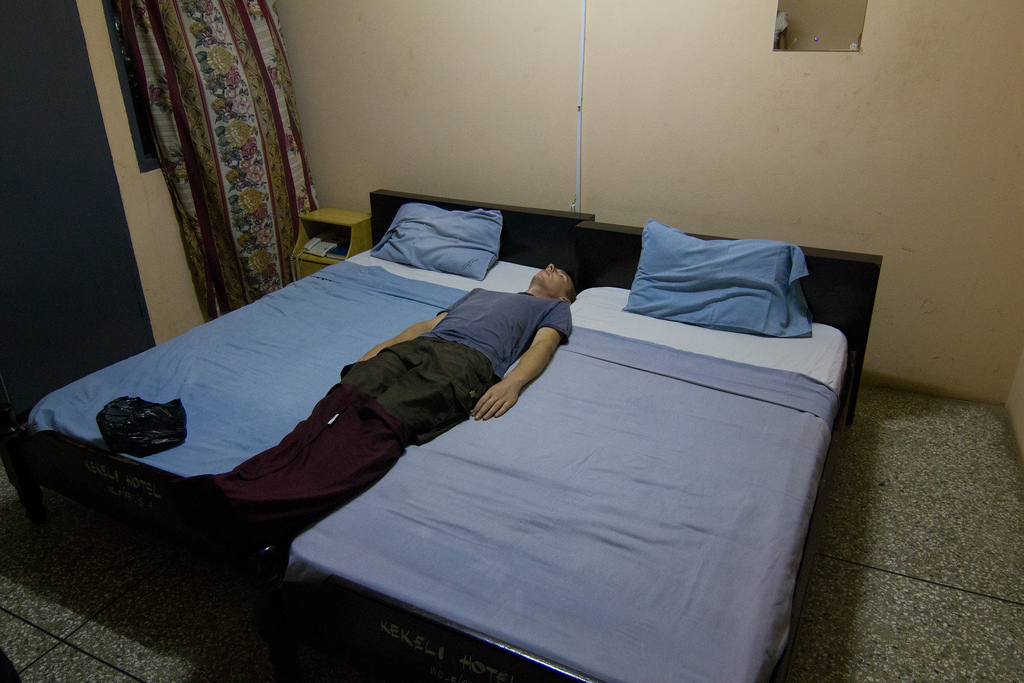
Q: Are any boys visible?
A: No, there are no boys.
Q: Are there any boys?
A: No, there are no boys.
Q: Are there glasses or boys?
A: No, there are no boys or glasses.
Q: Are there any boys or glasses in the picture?
A: No, there are no boys or glasses.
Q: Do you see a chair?
A: No, there are no chairs.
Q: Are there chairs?
A: No, there are no chairs.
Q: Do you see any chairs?
A: No, there are no chairs.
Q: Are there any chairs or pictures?
A: No, there are no chairs or pictures.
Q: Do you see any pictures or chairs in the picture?
A: No, there are no chairs or pictures.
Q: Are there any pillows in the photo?
A: Yes, there is a pillow.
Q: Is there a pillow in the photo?
A: Yes, there is a pillow.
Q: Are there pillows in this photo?
A: Yes, there is a pillow.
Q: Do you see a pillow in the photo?
A: Yes, there is a pillow.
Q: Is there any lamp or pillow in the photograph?
A: Yes, there is a pillow.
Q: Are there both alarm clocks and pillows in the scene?
A: No, there is a pillow but no alarm clocks.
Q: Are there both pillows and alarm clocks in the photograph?
A: No, there is a pillow but no alarm clocks.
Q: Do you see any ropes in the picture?
A: No, there are no ropes.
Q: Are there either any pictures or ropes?
A: No, there are no ropes or pictures.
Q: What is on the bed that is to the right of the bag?
A: The pillow is on the bed.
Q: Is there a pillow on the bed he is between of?
A: Yes, there is a pillow on the bed.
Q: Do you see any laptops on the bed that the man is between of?
A: No, there is a pillow on the bed.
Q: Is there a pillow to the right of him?
A: Yes, there is a pillow to the right of the man.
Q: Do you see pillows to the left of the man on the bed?
A: No, the pillow is to the right of the man.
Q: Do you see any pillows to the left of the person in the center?
A: No, the pillow is to the right of the man.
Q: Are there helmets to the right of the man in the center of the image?
A: No, there is a pillow to the right of the man.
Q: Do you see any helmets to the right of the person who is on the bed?
A: No, there is a pillow to the right of the man.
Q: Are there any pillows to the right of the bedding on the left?
A: Yes, there is a pillow to the right of the bedding.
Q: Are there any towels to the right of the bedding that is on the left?
A: No, there is a pillow to the right of the bedding.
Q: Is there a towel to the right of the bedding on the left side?
A: No, there is a pillow to the right of the bedding.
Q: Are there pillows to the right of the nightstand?
A: Yes, there is a pillow to the right of the nightstand.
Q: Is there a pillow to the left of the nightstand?
A: No, the pillow is to the right of the nightstand.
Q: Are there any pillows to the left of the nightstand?
A: No, the pillow is to the right of the nightstand.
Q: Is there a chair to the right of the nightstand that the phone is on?
A: No, there is a pillow to the right of the nightstand.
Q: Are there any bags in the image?
A: Yes, there is a bag.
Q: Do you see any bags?
A: Yes, there is a bag.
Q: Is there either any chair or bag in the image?
A: Yes, there is a bag.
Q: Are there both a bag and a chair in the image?
A: No, there is a bag but no chairs.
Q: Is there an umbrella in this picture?
A: No, there are no umbrellas.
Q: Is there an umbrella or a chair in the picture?
A: No, there are no umbrellas or chairs.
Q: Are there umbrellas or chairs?
A: No, there are no umbrellas or chairs.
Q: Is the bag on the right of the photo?
A: No, the bag is on the left of the image.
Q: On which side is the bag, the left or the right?
A: The bag is on the left of the image.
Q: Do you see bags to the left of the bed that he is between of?
A: Yes, there is a bag to the left of the bed.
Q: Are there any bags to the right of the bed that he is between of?
A: No, the bag is to the left of the bed.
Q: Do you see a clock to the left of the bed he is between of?
A: No, there is a bag to the left of the bed.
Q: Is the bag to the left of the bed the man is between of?
A: Yes, the bag is to the left of the bed.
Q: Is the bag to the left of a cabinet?
A: No, the bag is to the left of the bed.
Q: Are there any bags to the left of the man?
A: Yes, there is a bag to the left of the man.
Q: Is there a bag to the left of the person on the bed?
A: Yes, there is a bag to the left of the man.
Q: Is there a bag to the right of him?
A: No, the bag is to the left of the man.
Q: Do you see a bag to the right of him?
A: No, the bag is to the left of the man.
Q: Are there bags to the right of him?
A: No, the bag is to the left of the man.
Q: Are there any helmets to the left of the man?
A: No, there is a bag to the left of the man.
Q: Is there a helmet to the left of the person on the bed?
A: No, there is a bag to the left of the man.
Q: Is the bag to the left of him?
A: Yes, the bag is to the left of the man.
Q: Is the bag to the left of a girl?
A: No, the bag is to the left of the man.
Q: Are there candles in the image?
A: No, there are no candles.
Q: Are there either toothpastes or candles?
A: No, there are no candles or toothpastes.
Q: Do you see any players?
A: No, there are no players.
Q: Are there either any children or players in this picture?
A: No, there are no players or children.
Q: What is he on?
A: The man is on the bed.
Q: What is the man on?
A: The man is on the bed.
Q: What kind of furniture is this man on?
A: The man is on the bed.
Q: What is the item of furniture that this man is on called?
A: The piece of furniture is a bed.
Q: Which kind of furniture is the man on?
A: The man is on the bed.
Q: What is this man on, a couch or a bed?
A: The man is on a bed.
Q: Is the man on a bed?
A: Yes, the man is on a bed.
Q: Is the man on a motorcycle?
A: No, the man is on a bed.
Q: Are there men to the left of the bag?
A: No, the man is to the right of the bag.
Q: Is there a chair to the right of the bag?
A: No, there is a man to the right of the bag.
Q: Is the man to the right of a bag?
A: Yes, the man is to the right of a bag.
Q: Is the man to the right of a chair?
A: No, the man is to the right of a bag.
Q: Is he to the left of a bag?
A: No, the man is to the right of a bag.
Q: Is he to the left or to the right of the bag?
A: The man is to the right of the bag.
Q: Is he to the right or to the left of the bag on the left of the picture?
A: The man is to the right of the bag.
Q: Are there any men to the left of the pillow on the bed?
A: Yes, there is a man to the left of the pillow.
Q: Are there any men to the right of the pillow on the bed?
A: No, the man is to the left of the pillow.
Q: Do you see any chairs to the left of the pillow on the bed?
A: No, there is a man to the left of the pillow.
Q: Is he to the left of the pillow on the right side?
A: Yes, the man is to the left of the pillow.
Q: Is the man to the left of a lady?
A: No, the man is to the left of the pillow.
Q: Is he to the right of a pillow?
A: No, the man is to the left of a pillow.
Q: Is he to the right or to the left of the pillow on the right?
A: The man is to the left of the pillow.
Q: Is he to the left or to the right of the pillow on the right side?
A: The man is to the left of the pillow.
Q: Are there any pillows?
A: Yes, there is a pillow.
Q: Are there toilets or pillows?
A: Yes, there is a pillow.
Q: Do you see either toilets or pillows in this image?
A: Yes, there is a pillow.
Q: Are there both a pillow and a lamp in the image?
A: No, there is a pillow but no lamps.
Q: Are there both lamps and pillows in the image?
A: No, there is a pillow but no lamps.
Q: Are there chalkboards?
A: No, there are no chalkboards.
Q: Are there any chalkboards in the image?
A: No, there are no chalkboards.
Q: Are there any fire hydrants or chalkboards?
A: No, there are no chalkboards or fire hydrants.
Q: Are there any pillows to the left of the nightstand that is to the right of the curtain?
A: No, the pillow is to the right of the nightstand.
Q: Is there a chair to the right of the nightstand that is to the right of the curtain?
A: No, there is a pillow to the right of the nightstand.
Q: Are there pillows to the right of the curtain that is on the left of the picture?
A: Yes, there is a pillow to the right of the curtain.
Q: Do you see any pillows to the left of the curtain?
A: No, the pillow is to the right of the curtain.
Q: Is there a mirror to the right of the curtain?
A: No, there is a pillow to the right of the curtain.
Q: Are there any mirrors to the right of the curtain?
A: No, there is a pillow to the right of the curtain.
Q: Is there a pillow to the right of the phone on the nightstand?
A: Yes, there is a pillow to the right of the telephone.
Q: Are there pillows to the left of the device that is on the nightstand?
A: No, the pillow is to the right of the phone.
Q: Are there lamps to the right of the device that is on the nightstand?
A: No, there is a pillow to the right of the telephone.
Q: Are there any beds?
A: Yes, there is a bed.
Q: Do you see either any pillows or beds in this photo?
A: Yes, there is a bed.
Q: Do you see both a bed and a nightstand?
A: Yes, there are both a bed and a nightstand.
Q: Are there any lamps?
A: No, there are no lamps.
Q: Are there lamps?
A: No, there are no lamps.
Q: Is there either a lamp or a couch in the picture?
A: No, there are no lamps or couches.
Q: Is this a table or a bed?
A: This is a bed.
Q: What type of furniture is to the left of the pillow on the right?
A: The piece of furniture is a bed.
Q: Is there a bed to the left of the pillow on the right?
A: Yes, there is a bed to the left of the pillow.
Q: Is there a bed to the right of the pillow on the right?
A: No, the bed is to the left of the pillow.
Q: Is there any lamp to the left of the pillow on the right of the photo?
A: No, there is a bed to the left of the pillow.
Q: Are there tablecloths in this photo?
A: No, there are no tablecloths.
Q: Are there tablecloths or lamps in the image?
A: No, there are no tablecloths or lamps.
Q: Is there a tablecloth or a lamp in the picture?
A: No, there are no tablecloths or lamps.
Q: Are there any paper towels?
A: No, there are no paper towels.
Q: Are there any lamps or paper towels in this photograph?
A: No, there are no paper towels or lamps.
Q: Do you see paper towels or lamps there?
A: No, there are no paper towels or lamps.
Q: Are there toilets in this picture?
A: No, there are no toilets.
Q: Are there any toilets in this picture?
A: No, there are no toilets.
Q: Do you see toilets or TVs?
A: No, there are no toilets or tvs.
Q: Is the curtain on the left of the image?
A: Yes, the curtain is on the left of the image.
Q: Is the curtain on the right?
A: No, the curtain is on the left of the image.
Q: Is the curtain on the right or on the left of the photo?
A: The curtain is on the left of the image.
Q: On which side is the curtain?
A: The curtain is on the left of the image.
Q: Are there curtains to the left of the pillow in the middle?
A: Yes, there is a curtain to the left of the pillow.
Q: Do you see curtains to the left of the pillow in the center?
A: Yes, there is a curtain to the left of the pillow.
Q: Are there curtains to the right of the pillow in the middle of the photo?
A: No, the curtain is to the left of the pillow.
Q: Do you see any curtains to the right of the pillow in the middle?
A: No, the curtain is to the left of the pillow.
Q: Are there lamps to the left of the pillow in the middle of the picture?
A: No, there is a curtain to the left of the pillow.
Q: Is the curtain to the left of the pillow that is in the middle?
A: Yes, the curtain is to the left of the pillow.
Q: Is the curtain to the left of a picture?
A: No, the curtain is to the left of the pillow.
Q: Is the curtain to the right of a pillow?
A: No, the curtain is to the left of a pillow.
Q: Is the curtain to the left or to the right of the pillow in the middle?
A: The curtain is to the left of the pillow.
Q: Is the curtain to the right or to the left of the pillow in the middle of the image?
A: The curtain is to the left of the pillow.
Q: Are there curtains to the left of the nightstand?
A: Yes, there is a curtain to the left of the nightstand.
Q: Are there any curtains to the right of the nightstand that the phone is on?
A: No, the curtain is to the left of the nightstand.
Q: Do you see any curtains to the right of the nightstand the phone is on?
A: No, the curtain is to the left of the nightstand.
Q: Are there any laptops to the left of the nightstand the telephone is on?
A: No, there is a curtain to the left of the nightstand.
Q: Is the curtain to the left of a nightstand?
A: Yes, the curtain is to the left of a nightstand.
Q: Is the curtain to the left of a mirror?
A: No, the curtain is to the left of a nightstand.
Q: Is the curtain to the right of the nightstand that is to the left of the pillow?
A: No, the curtain is to the left of the nightstand.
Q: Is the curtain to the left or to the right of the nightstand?
A: The curtain is to the left of the nightstand.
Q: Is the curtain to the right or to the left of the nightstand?
A: The curtain is to the left of the nightstand.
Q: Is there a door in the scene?
A: Yes, there is a door.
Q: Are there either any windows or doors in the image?
A: Yes, there is a door.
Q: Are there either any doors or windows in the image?
A: Yes, there is a door.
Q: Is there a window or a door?
A: Yes, there is a door.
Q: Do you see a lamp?
A: No, there are no lamps.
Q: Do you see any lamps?
A: No, there are no lamps.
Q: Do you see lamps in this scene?
A: No, there are no lamps.